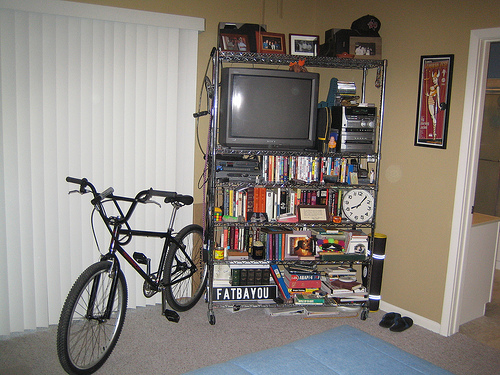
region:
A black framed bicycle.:
[52, 173, 209, 371]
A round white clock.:
[340, 190, 375, 217]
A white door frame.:
[437, 25, 492, 341]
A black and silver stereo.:
[337, 102, 372, 149]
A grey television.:
[224, 65, 318, 148]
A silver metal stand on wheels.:
[204, 53, 388, 321]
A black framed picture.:
[412, 52, 455, 147]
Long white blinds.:
[4, 2, 204, 334]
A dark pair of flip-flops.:
[380, 308, 412, 336]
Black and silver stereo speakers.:
[219, 22, 369, 53]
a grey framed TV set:
[222, 65, 319, 150]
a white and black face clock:
[343, 189, 373, 222]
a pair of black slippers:
[378, 310, 411, 332]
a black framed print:
[413, 50, 455, 152]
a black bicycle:
[55, 171, 210, 373]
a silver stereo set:
[339, 101, 378, 151]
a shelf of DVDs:
[258, 155, 348, 183]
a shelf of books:
[212, 182, 343, 218]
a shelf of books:
[219, 224, 288, 261]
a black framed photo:
[287, 30, 322, 56]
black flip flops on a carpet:
[378, 307, 414, 333]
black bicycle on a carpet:
[53, 175, 208, 374]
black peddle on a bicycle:
[162, 307, 182, 322]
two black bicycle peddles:
[129, 248, 183, 321]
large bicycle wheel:
[55, 258, 130, 374]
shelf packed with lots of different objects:
[214, 187, 374, 224]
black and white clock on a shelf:
[336, 189, 376, 223]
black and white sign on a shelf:
[212, 285, 278, 300]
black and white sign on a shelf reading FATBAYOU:
[210, 285, 277, 300]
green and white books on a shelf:
[293, 292, 325, 305]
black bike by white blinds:
[52, 173, 211, 355]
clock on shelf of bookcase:
[340, 190, 369, 223]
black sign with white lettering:
[214, 275, 277, 310]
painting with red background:
[407, 52, 452, 148]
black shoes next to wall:
[378, 310, 414, 327]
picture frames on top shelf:
[209, 20, 384, 60]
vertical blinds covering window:
[0, 5, 195, 315]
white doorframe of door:
[440, 25, 499, 335]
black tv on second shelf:
[214, 66, 319, 144]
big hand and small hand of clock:
[345, 193, 370, 211]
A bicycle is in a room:
[20, 30, 452, 370]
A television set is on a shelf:
[41, 17, 447, 372]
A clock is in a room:
[31, 45, 469, 365]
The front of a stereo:
[340, 102, 375, 152]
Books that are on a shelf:
[270, 153, 315, 179]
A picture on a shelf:
[256, 31, 283, 54]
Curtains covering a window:
[3, 30, 168, 172]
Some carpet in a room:
[150, 323, 207, 356]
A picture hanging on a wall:
[420, 55, 445, 147]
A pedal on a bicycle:
[162, 309, 179, 324]